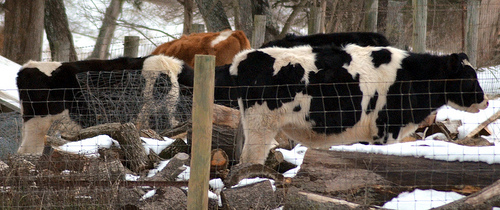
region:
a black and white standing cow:
[233, 42, 487, 173]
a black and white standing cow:
[14, 59, 190, 154]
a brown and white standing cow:
[150, 27, 249, 67]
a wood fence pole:
[191, 52, 213, 208]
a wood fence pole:
[121, 34, 138, 55]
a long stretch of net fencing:
[0, 77, 498, 208]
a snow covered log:
[298, 137, 498, 185]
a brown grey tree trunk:
[1, 1, 46, 59]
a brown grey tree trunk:
[43, 0, 75, 60]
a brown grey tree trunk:
[92, 0, 122, 57]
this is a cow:
[217, 17, 497, 199]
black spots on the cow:
[286, 50, 373, 125]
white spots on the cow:
[350, 50, 401, 104]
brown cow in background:
[140, 15, 259, 86]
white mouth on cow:
[455, 84, 492, 118]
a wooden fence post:
[178, 30, 225, 206]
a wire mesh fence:
[0, 45, 499, 207]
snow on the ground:
[363, 116, 499, 185]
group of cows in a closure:
[20, 17, 482, 207]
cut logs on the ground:
[37, 108, 245, 208]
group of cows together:
[0, 38, 482, 128]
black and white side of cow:
[303, 41, 401, 113]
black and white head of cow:
[438, 53, 489, 115]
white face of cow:
[470, 99, 493, 113]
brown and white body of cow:
[149, 22, 243, 72]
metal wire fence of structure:
[190, 73, 430, 208]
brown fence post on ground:
[183, 53, 213, 208]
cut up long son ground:
[23, 133, 154, 208]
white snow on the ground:
[389, 129, 487, 171]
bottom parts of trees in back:
[350, 0, 496, 25]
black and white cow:
[270, 62, 492, 142]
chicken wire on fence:
[97, 86, 114, 136]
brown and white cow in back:
[175, 48, 208, 53]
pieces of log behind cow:
[216, 107, 249, 180]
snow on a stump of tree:
[58, 140, 80, 148]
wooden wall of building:
[469, 22, 473, 25]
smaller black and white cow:
[51, 93, 125, 125]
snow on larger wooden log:
[416, 148, 482, 190]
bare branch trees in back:
[123, 10, 161, 16]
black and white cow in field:
[222, 35, 488, 172]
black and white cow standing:
[12, 49, 217, 172]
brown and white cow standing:
[136, 25, 254, 87]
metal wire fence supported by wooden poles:
[2, 46, 497, 191]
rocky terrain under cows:
[7, 140, 496, 200]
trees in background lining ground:
[10, 0, 495, 82]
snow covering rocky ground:
[58, 66, 498, 208]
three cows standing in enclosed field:
[12, 5, 488, 186]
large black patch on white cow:
[295, 66, 367, 136]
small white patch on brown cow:
[207, 30, 234, 52]